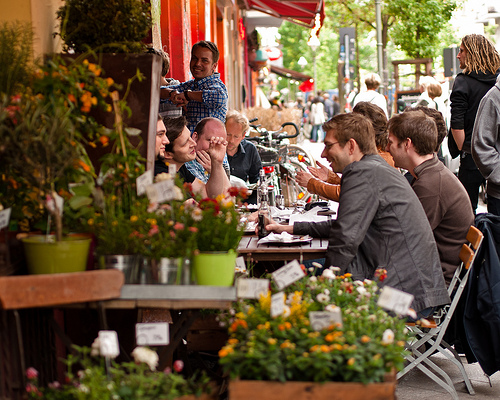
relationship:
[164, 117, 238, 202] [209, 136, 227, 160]
man has hand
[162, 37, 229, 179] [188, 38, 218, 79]
man has head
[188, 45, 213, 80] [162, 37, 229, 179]
face of man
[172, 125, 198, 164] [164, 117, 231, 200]
face of man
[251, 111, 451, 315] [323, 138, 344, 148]
man wearing eye glasses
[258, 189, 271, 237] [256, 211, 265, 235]
bottle has label